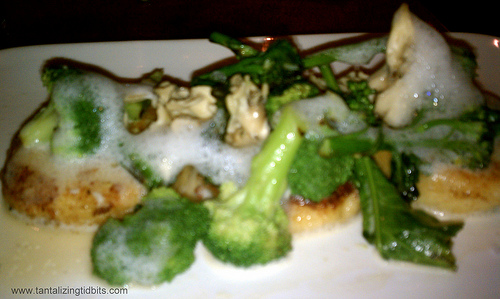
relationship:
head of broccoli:
[192, 192, 281, 258] [198, 122, 310, 297]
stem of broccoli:
[242, 122, 311, 191] [198, 122, 310, 297]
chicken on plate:
[3, 164, 145, 258] [32, 36, 492, 291]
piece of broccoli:
[257, 134, 313, 248] [198, 122, 310, 297]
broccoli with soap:
[198, 122, 310, 297] [161, 117, 219, 166]